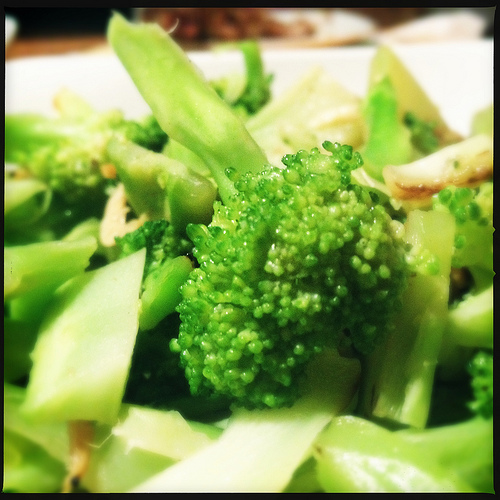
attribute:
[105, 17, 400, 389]
food — green, broccoli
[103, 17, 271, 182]
broccoli — moist, wet, green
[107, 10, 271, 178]
stem — out, slanted, cut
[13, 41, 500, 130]
plate — white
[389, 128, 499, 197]
stem — fried, brown, small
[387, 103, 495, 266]
vegetable — fried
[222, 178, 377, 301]
grain — reflecting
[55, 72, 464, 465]
surface — shiny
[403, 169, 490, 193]
char — brown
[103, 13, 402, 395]
floret — bumpy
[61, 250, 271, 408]
vegetables — Fresh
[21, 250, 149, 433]
stem — smooth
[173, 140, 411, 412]
broccoli — Freshly rinsed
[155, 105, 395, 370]
broccoli — Fresh, stir-fired 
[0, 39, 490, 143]
plate — white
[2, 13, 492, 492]
broccoli — chopped 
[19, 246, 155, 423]
spear — sharp edge